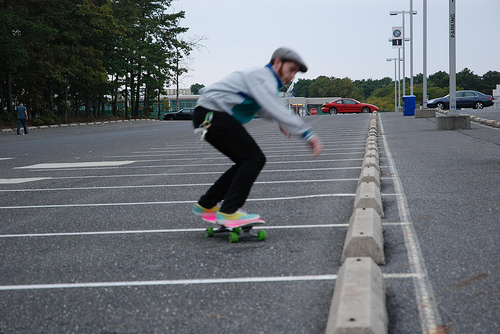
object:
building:
[60, 88, 346, 119]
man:
[17, 102, 29, 136]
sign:
[310, 108, 317, 116]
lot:
[3, 110, 498, 330]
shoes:
[216, 209, 262, 225]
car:
[419, 89, 494, 111]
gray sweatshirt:
[194, 64, 318, 142]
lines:
[0, 157, 366, 292]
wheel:
[255, 227, 268, 241]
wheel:
[226, 229, 239, 243]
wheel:
[205, 224, 213, 238]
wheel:
[233, 227, 241, 234]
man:
[192, 46, 323, 230]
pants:
[192, 106, 267, 214]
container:
[402, 95, 416, 116]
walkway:
[380, 107, 498, 332]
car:
[320, 97, 377, 115]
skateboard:
[201, 210, 271, 243]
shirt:
[16, 106, 26, 119]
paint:
[44, 169, 198, 293]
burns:
[277, 60, 284, 82]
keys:
[192, 110, 216, 143]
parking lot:
[2, 105, 497, 331]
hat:
[272, 46, 308, 73]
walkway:
[379, 104, 478, 332]